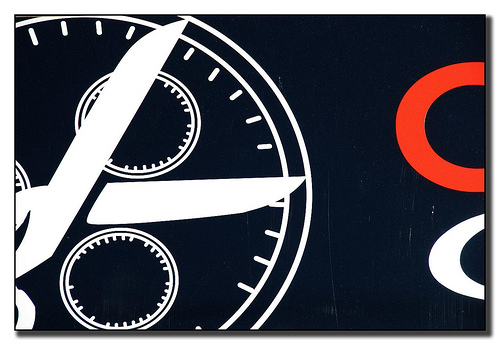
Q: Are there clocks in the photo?
A: Yes, there is a clock.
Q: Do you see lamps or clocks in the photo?
A: Yes, there is a clock.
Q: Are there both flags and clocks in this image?
A: No, there is a clock but no flags.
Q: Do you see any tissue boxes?
A: No, there are no tissue boxes.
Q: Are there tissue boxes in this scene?
A: No, there are no tissue boxes.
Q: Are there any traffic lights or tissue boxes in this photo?
A: No, there are no tissue boxes or traffic lights.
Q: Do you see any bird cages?
A: No, there are no bird cages.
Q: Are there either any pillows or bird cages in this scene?
A: No, there are no bird cages or pillows.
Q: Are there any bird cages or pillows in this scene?
A: No, there are no bird cages or pillows.